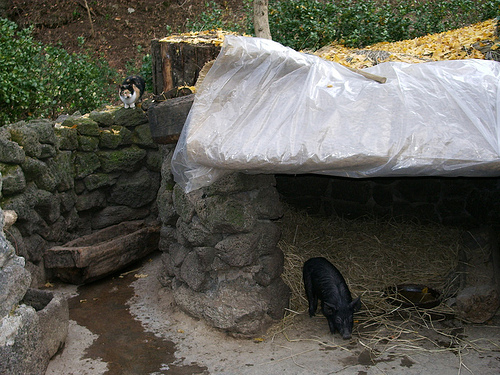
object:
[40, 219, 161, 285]
trough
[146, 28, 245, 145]
mulch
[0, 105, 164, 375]
wall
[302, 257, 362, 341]
boar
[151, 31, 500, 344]
home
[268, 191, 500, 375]
hay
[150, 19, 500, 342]
cave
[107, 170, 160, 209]
rock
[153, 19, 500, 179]
covering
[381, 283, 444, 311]
water bowl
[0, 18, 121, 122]
bush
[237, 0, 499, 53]
bush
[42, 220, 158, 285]
water basin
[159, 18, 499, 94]
leaves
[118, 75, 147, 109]
black cat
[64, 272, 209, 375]
water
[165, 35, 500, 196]
tarp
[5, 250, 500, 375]
ground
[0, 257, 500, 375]
floor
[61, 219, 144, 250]
food